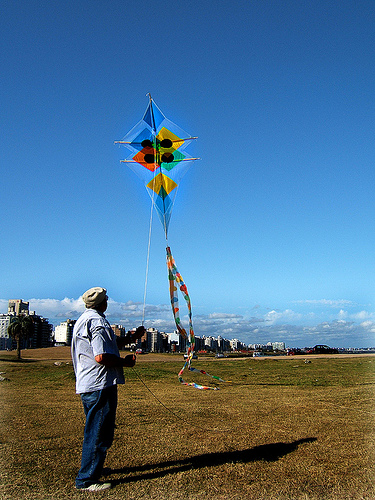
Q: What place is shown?
A: It is a park.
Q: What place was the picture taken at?
A: It was taken at the park.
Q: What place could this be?
A: It is a park.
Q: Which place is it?
A: It is a park.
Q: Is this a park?
A: Yes, it is a park.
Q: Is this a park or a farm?
A: It is a park.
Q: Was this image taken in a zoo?
A: No, the picture was taken in a park.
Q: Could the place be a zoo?
A: No, it is a park.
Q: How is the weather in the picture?
A: It is clear.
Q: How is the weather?
A: It is clear.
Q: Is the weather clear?
A: Yes, it is clear.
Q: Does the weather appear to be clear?
A: Yes, it is clear.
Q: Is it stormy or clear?
A: It is clear.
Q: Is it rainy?
A: No, it is clear.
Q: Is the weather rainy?
A: No, it is clear.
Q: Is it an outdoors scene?
A: Yes, it is outdoors.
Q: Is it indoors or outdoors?
A: It is outdoors.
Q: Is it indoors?
A: No, it is outdoors.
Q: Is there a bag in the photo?
A: No, there are no bags.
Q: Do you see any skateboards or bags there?
A: No, there are no bags or skateboards.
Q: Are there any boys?
A: No, there are no boys.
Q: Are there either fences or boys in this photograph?
A: No, there are no boys or fences.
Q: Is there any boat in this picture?
A: No, there are no boats.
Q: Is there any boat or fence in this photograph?
A: No, there are no boats or fences.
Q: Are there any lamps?
A: No, there are no lamps.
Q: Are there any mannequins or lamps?
A: No, there are no lamps or mannequins.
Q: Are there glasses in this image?
A: No, there are no glasses.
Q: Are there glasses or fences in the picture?
A: No, there are no glasses or fences.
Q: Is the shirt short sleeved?
A: Yes, the shirt is short sleeved.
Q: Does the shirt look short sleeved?
A: Yes, the shirt is short sleeved.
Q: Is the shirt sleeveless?
A: No, the shirt is short sleeved.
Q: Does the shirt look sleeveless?
A: No, the shirt is short sleeved.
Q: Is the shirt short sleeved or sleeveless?
A: The shirt is short sleeved.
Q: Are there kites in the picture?
A: Yes, there is a kite.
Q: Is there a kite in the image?
A: Yes, there is a kite.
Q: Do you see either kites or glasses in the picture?
A: Yes, there is a kite.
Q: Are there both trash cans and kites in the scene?
A: No, there is a kite but no trash cans.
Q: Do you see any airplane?
A: No, there are no airplanes.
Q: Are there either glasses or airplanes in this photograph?
A: No, there are no airplanes or glasses.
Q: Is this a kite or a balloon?
A: This is a kite.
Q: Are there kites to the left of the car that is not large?
A: Yes, there is a kite to the left of the car.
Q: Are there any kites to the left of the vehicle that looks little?
A: Yes, there is a kite to the left of the car.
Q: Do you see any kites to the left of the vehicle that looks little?
A: Yes, there is a kite to the left of the car.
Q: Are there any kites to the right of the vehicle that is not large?
A: No, the kite is to the left of the car.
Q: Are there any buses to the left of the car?
A: No, there is a kite to the left of the car.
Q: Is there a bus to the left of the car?
A: No, there is a kite to the left of the car.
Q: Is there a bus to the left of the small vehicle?
A: No, there is a kite to the left of the car.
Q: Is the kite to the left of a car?
A: Yes, the kite is to the left of a car.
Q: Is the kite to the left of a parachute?
A: No, the kite is to the left of a car.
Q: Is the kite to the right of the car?
A: No, the kite is to the left of the car.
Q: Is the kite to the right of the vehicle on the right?
A: No, the kite is to the left of the car.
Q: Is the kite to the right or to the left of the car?
A: The kite is to the left of the car.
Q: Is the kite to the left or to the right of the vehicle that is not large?
A: The kite is to the left of the car.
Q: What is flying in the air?
A: The kite is flying in the air.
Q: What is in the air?
A: The kite is in the air.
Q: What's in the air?
A: The kite is in the air.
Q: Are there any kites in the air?
A: Yes, there is a kite in the air.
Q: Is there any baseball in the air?
A: No, there is a kite in the air.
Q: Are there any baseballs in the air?
A: No, there is a kite in the air.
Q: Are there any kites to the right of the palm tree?
A: Yes, there is a kite to the right of the palm tree.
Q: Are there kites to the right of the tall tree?
A: Yes, there is a kite to the right of the palm tree.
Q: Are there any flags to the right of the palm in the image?
A: No, there is a kite to the right of the palm.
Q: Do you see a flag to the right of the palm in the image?
A: No, there is a kite to the right of the palm.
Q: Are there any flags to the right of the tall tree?
A: No, there is a kite to the right of the palm.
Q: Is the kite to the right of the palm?
A: Yes, the kite is to the right of the palm.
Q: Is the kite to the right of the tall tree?
A: Yes, the kite is to the right of the palm.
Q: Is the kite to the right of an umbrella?
A: No, the kite is to the right of the palm.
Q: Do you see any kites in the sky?
A: Yes, there is a kite in the sky.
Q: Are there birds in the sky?
A: No, there is a kite in the sky.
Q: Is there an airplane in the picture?
A: No, there are no airplanes.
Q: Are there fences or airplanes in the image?
A: No, there are no airplanes or fences.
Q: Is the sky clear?
A: Yes, the sky is clear.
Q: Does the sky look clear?
A: Yes, the sky is clear.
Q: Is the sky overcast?
A: No, the sky is clear.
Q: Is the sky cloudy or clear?
A: The sky is clear.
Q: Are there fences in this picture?
A: No, there are no fences.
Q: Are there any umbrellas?
A: No, there are no umbrellas.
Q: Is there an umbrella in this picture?
A: No, there are no umbrellas.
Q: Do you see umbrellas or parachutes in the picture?
A: No, there are no umbrellas or parachutes.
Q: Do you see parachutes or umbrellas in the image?
A: No, there are no umbrellas or parachutes.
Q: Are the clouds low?
A: Yes, the clouds are low.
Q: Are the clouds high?
A: No, the clouds are low.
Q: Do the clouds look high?
A: No, the clouds are low.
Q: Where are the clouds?
A: The clouds are in the sky.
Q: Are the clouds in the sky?
A: Yes, the clouds are in the sky.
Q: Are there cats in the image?
A: No, there are no cats.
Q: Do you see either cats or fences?
A: No, there are no cats or fences.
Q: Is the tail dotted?
A: Yes, the tail is dotted.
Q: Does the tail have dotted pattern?
A: Yes, the tail is dotted.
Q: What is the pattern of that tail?
A: The tail is dotted.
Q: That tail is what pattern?
A: The tail is dotted.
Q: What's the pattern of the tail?
A: The tail is dotted.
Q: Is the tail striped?
A: No, the tail is dotted.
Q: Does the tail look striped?
A: No, the tail is dotted.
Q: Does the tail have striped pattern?
A: No, the tail is dotted.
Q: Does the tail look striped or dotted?
A: The tail is dotted.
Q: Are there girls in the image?
A: No, there are no girls.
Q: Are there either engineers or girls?
A: No, there are no girls or engineers.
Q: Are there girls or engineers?
A: No, there are no girls or engineers.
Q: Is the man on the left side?
A: Yes, the man is on the left of the image.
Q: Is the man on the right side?
A: No, the man is on the left of the image.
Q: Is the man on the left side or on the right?
A: The man is on the left of the image.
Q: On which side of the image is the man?
A: The man is on the left of the image.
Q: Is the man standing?
A: Yes, the man is standing.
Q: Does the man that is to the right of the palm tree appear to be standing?
A: Yes, the man is standing.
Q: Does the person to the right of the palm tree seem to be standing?
A: Yes, the man is standing.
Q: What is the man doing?
A: The man is standing.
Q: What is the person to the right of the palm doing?
A: The man is standing.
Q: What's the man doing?
A: The man is standing.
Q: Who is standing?
A: The man is standing.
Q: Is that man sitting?
A: No, the man is standing.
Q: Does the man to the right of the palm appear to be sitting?
A: No, the man is standing.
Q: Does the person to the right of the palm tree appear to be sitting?
A: No, the man is standing.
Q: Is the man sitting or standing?
A: The man is standing.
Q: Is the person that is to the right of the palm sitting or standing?
A: The man is standing.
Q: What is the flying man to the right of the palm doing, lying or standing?
A: The man is standing.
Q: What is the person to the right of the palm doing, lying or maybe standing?
A: The man is standing.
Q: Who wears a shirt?
A: The man wears a shirt.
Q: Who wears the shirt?
A: The man wears a shirt.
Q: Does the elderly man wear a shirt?
A: Yes, the man wears a shirt.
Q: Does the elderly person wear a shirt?
A: Yes, the man wears a shirt.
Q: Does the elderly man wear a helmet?
A: No, the man wears a shirt.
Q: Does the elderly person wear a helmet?
A: No, the man wears a shirt.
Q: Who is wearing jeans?
A: The man is wearing jeans.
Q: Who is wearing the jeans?
A: The man is wearing jeans.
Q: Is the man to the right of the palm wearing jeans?
A: Yes, the man is wearing jeans.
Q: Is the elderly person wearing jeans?
A: Yes, the man is wearing jeans.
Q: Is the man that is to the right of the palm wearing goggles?
A: No, the man is wearing jeans.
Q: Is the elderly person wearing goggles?
A: No, the man is wearing jeans.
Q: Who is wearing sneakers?
A: The man is wearing sneakers.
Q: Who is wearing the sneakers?
A: The man is wearing sneakers.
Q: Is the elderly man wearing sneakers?
A: Yes, the man is wearing sneakers.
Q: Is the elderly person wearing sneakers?
A: Yes, the man is wearing sneakers.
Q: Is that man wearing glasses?
A: No, the man is wearing sneakers.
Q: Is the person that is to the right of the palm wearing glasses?
A: No, the man is wearing sneakers.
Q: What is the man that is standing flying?
A: The man is flying the kite.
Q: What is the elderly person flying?
A: The man is flying the kite.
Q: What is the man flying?
A: The man is flying the kite.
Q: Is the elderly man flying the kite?
A: Yes, the man is flying the kite.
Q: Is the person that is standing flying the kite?
A: Yes, the man is flying the kite.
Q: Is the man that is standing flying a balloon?
A: No, the man is flying the kite.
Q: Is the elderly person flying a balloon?
A: No, the man is flying the kite.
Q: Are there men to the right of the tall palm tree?
A: Yes, there is a man to the right of the palm.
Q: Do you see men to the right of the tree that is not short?
A: Yes, there is a man to the right of the palm.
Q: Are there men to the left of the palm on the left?
A: No, the man is to the right of the palm tree.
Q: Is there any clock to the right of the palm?
A: No, there is a man to the right of the palm.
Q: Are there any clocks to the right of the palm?
A: No, there is a man to the right of the palm.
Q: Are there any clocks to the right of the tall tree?
A: No, there is a man to the right of the palm.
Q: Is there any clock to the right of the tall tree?
A: No, there is a man to the right of the palm.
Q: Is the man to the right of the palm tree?
A: Yes, the man is to the right of the palm tree.